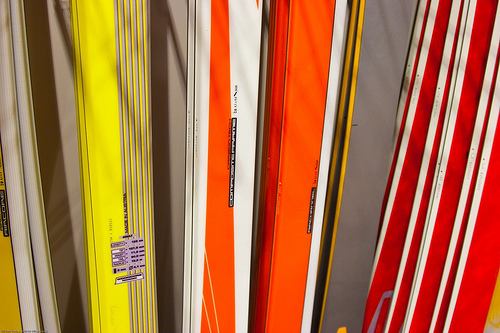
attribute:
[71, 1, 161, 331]
blinds — yellow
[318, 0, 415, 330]
blinds — grey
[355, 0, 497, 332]
red blints — long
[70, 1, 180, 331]
yellow board — long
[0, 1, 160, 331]
blinds — colorful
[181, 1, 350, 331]
blinds — orange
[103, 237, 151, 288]
signs — white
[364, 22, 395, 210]
board — thin, gray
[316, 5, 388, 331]
stripe — gray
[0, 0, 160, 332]
sign — white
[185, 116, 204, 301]
stripe — white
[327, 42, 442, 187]
board — thin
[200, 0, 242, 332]
stripe — red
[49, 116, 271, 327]
blind — vertical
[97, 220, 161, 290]
signs — white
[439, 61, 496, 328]
line — white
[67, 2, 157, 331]
yellow board — long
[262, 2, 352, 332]
blind — vertical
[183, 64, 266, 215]
board — red, orange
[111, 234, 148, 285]
signs — white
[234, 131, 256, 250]
white stripe — long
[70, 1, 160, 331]
stripe — yellow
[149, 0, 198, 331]
stripe — gray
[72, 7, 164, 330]
board — yellow